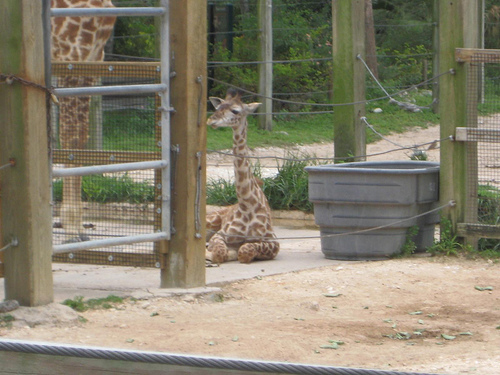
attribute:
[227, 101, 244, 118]
eyes — open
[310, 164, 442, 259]
bucket — silver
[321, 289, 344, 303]
stone — small, grey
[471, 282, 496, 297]
stone — small, grey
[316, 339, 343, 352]
stone — small, grey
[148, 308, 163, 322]
stone — small, grey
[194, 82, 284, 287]
giraffe — baby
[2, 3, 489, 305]
fence — chain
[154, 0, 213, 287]
post — wooden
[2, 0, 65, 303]
post — wooden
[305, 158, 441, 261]
bucket — silver,  Silver 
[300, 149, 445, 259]
bucket — Silver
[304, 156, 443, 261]
plastic container —  plastic 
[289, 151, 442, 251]
bin — gray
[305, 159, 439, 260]
container — large, blue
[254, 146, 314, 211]
grass — green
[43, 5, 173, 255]
gate — gray, metal, closed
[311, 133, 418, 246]
bucket — silver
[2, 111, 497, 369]
dirt — light brown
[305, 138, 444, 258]
bucket — silver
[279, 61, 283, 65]
leaf — lush, green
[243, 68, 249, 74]
leaf — lush, green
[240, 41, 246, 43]
leaf — lush, green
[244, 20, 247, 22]
leaf — lush, green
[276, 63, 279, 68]
leaf — lush, green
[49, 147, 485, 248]
grass — tall, green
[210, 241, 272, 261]
legs — long, spindly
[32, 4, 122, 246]
giraffe — big , standing 